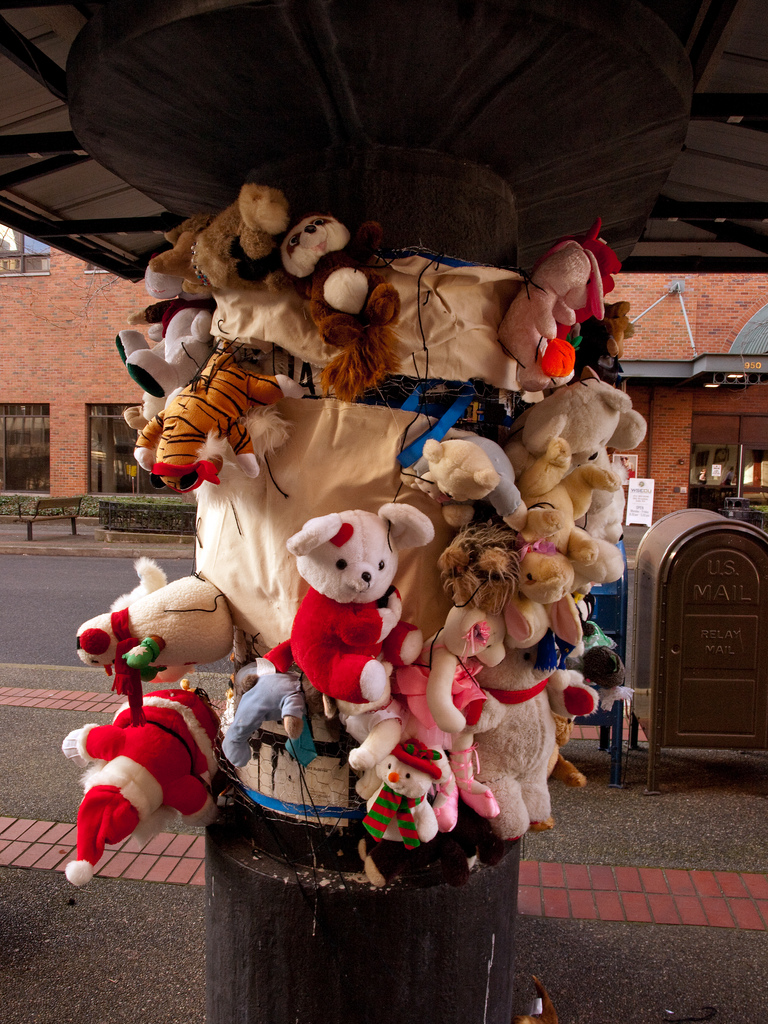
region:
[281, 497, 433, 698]
Stuffed red and white teddy bear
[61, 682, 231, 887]
Stuffed Santa Claus doll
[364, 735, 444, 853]
Stuffed snowman doll with red and green scarf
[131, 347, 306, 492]
Stuffed tiger doll with red headband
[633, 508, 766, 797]
Brown mailbox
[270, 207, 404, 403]
Stuffed brown and white raccoon doll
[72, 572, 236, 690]
Stuffed snowman doll wearing earmuffs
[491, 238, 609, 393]
Stuffed pink rabbit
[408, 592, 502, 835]
Teddy bear dressed as ballerina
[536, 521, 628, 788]
Blue mailbox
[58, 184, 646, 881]
Many stuffed animals attached to a collumn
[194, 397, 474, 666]
A piece of brown paper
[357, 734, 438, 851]
a plush snowman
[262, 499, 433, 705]
a plush teddy bear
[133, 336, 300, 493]
a plush tiger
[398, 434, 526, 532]
a plush teddy bear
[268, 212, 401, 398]
a plush red panda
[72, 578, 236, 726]
a plush snowman attached facing down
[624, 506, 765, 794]
a brown mailbox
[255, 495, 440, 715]
THE BEAR IS RED AND WHITE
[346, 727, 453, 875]
THE SNOWMAN IS SMALL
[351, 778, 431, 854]
THE SNOW MAN IS WEARING A STRIPED SCARF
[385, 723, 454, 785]
THE SNOWMAN IS WEARING A RED HAT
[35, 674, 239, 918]
THE SANTA IS HANGING SIDE WAYS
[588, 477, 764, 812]
THE MAIL BOX IS BROWN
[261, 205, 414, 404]
THE SQUIRREL IS BROWN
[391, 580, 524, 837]
THE BUNNY IS A BALLERINA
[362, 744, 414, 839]
stuffed animal on the pipe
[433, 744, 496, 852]
stuffed animal on the pipe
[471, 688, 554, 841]
stuffed animal on the pipe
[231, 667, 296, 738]
stuffed animal on the pipe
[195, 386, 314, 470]
stuffed animal on the pipe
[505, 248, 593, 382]
stuffed animal on the pipe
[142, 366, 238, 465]
stuffed animal on the pipe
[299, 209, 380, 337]
stuffed animal on the pipe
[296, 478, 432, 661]
a teddy bear on the pole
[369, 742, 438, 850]
a teddy bear on the pole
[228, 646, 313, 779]
a teddy bear on the pole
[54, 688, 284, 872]
a teddy bear on the pole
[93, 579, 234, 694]
a teddy bear on the pole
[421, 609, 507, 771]
a teddy bear on the pole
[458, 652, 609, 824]
a teddy bear on the pole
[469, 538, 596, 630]
a teddy bear on the pole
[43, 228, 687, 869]
stuffed animals near each other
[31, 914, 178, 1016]
ground under stuffed animals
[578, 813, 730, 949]
red tile on ground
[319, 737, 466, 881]
snowman stuffed animal in group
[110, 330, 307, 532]
tiger attached to the object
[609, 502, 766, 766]
mailbox near the stuffed animals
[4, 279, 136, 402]
red bricks on building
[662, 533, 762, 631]
words on the mailbox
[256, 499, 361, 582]
ear of the stuffed animal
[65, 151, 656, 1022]
stuffed animals on a pole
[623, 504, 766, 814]
a brown mailbox on a sidewalk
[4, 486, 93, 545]
empty street bench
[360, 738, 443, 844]
small snowman stuffed animal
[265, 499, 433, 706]
a white and red stuffed Christmas mouse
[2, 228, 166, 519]
a red brick building